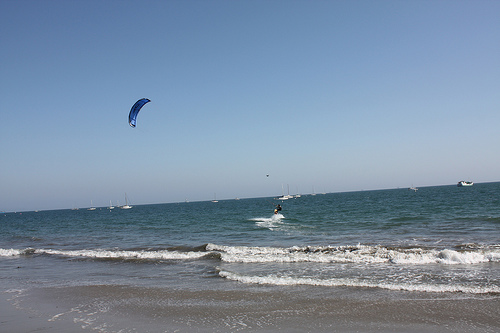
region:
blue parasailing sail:
[117, 84, 162, 143]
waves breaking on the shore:
[9, 237, 492, 297]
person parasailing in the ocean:
[111, 88, 305, 229]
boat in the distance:
[446, 171, 486, 200]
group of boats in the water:
[49, 177, 149, 219]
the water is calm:
[0, 165, 499, 242]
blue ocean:
[1, 174, 497, 259]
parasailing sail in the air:
[105, 72, 179, 157]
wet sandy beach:
[6, 260, 491, 326]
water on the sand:
[12, 262, 486, 331]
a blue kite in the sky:
[121, 93, 156, 131]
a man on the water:
[268, 197, 287, 217]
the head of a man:
[275, 200, 284, 208]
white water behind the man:
[245, 207, 289, 234]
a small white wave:
[0, 240, 499, 275]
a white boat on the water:
[114, 186, 138, 213]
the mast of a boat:
[120, 189, 132, 206]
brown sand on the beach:
[1, 265, 499, 331]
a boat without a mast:
[453, 174, 481, 190]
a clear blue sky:
[0, 0, 499, 217]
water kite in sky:
[101, 76, 169, 174]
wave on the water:
[83, 246, 255, 273]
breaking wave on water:
[187, 242, 254, 274]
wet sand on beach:
[258, 299, 393, 329]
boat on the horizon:
[451, 160, 483, 209]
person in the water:
[265, 197, 297, 220]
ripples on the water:
[370, 205, 450, 237]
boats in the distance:
[90, 185, 140, 215]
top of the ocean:
[345, 195, 440, 230]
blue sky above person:
[300, 65, 430, 162]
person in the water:
[266, 201, 288, 223]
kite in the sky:
[115, 96, 164, 134]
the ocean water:
[218, 231, 388, 309]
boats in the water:
[88, 193, 150, 210]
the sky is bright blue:
[278, 42, 428, 136]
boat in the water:
[452, 171, 487, 193]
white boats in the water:
[273, 178, 306, 203]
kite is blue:
[119, 99, 164, 133]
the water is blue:
[388, 196, 475, 241]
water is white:
[27, 239, 134, 269]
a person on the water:
[268, 197, 285, 220]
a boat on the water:
[116, 187, 137, 212]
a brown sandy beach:
[4, 282, 498, 332]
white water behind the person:
[247, 209, 288, 235]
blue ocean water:
[0, 180, 499, 256]